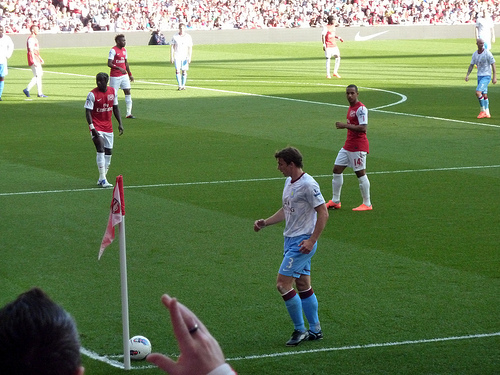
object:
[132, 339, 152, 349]
logos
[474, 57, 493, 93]
uniform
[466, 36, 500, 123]
man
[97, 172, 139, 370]
flag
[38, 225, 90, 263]
field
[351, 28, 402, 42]
logo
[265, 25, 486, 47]
wall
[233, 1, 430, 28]
fans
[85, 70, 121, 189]
uniforms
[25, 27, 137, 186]
men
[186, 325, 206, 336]
ring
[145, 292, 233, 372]
hand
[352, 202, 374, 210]
cleats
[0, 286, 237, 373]
cameraman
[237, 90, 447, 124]
lines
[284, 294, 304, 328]
socks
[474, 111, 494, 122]
shoes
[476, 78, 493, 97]
pants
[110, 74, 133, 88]
pants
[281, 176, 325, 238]
shirt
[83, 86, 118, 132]
shirts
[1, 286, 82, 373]
head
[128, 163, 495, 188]
stripes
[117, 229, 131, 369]
pole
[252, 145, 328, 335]
player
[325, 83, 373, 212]
player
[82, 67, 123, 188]
player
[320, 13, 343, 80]
player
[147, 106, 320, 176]
grass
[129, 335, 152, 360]
ball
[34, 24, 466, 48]
stands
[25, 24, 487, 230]
people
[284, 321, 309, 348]
shoes